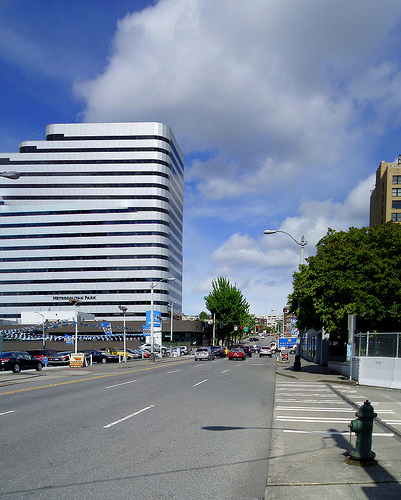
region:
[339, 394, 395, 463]
a green fire hydrant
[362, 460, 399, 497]
a shadow of a fire hydrant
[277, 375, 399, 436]
a cross walk across street white pattern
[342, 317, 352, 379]
a walk cross pole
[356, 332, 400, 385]
a wire fence with a white background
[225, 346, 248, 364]
a red car driving in traffic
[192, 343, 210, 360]
a silver car parked on street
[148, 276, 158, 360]
a light pole across street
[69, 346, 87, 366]
a yellow sign on pole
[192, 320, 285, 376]
many cars driving on street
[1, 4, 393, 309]
the sky is blue.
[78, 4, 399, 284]
The clouds are white.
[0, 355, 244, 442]
The lines on the street are white and yellow.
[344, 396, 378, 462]
Fire hydrant is green.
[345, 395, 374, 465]
Fire hydrant on the sidewalk.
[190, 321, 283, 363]
Cars stopped at the light.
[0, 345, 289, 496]
The street is concrete.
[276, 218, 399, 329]
The trees are green.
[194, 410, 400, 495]
Shadows on the sidewalk.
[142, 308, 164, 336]
The sign is blue.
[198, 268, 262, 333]
a leafy green tree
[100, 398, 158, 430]
a white line on the road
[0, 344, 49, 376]
a black car on the road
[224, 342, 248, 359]
a red car on the road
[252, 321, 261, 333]
a bank of traffic lights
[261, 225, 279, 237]
a street light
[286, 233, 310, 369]
a gray street light pole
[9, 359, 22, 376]
the wheel of a car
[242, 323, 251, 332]
a green traffic sign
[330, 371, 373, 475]
Fire hydrant on side of road.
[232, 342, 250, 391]
Red car in street.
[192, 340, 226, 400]
Silver car in street.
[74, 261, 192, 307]
Large building on the left side.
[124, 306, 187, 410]
Honda dealership on the left side.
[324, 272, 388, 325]
Green leaves on trees.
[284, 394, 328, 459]
White lines on concrete.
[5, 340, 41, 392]
Black car on side or road.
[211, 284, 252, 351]
Trees line side of road.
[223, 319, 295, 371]
Cars stopped at stop light.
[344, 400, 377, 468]
a fire hydrant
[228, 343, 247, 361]
a red car in the street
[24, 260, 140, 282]
a section of a white building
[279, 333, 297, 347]
a blue sign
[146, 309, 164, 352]
a honda dealership sign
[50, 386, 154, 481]
a section of the street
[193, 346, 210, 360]
a grey car in the street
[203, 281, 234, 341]
a tree near a street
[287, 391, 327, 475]
a section of a sidewalk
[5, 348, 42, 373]
a black car parked at a dealership